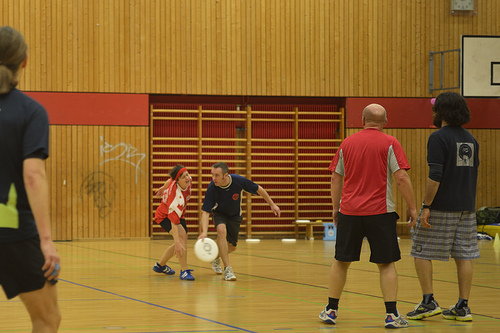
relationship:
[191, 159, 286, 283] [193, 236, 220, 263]
man holding frisbee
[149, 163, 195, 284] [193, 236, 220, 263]
woman playing frisbee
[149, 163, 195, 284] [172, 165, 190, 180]
woman wearing headband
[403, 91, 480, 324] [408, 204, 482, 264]
man wearing shorts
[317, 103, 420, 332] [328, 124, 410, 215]
man wearing shirt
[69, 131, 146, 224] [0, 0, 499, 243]
graffiti on wall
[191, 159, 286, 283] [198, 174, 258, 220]
man wearing shirt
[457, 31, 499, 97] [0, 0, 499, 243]
basketball goal on wall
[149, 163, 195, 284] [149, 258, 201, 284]
woman wearing sneakers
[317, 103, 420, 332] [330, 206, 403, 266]
man wearing shorts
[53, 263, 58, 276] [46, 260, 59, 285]
wrap on finger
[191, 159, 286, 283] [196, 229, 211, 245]
man has right hand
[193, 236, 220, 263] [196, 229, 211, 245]
frisbee in right hand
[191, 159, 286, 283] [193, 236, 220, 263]
man playing frisbee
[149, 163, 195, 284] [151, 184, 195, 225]
woman wearing shirt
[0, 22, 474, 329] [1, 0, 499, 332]
people in gym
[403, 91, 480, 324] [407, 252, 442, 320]
man has left leg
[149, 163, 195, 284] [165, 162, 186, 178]
woman has hair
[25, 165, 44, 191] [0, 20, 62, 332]
elbow of person